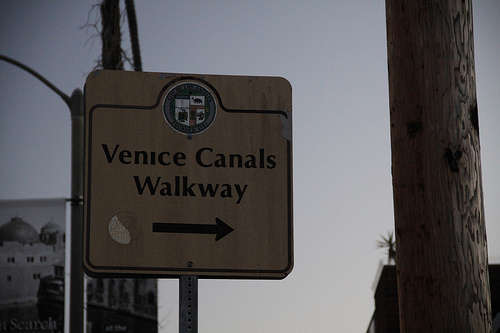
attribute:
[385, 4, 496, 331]
utility pole — wooden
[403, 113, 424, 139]
spot — dark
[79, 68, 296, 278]
sign — tan colored, brown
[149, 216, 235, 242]
arrow — black, pointing right, giving directions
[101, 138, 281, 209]
venice canal walkway — in english, black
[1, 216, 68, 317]
picture — of building, of historic building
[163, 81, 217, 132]
seal — round, green, white, yellow, from city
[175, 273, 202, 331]
pole — metal, light pole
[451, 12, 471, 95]
pattern — intricate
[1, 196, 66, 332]
banner — in background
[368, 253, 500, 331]
building — in background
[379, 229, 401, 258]
plant — palm tree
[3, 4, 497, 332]
sky — hues of gray, clear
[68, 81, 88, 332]
post — tall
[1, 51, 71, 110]
extension — curved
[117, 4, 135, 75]
twig — bare